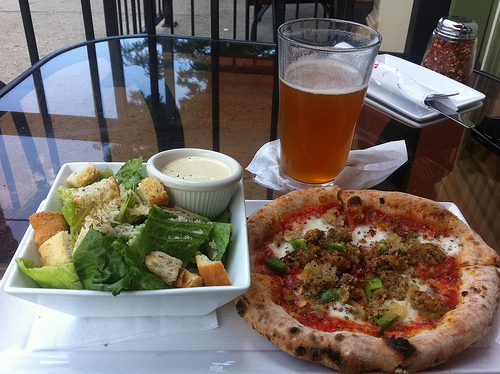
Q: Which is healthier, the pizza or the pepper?
A: The pepper is healthier than the pizza.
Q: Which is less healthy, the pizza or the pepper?
A: The pizza is less healthy than the pepper.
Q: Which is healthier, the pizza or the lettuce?
A: The lettuce is healthier than the pizza.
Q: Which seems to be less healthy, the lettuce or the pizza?
A: The pizza is less healthy than the lettuce.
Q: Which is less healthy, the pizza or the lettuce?
A: The pizza is less healthy than the lettuce.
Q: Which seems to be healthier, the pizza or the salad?
A: The salad is healthier than the pizza.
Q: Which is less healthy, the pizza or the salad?
A: The pizza is less healthy than the salad.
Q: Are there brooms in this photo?
A: No, there are no brooms.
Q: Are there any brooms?
A: No, there are no brooms.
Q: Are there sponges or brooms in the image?
A: No, there are no brooms or sponges.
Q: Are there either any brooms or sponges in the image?
A: No, there are no brooms or sponges.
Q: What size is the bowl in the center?
A: The bowl is small.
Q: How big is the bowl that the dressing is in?
A: The bowl is small.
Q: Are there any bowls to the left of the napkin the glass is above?
A: Yes, there is a bowl to the left of the napkin.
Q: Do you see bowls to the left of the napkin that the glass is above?
A: Yes, there is a bowl to the left of the napkin.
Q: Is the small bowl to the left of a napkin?
A: Yes, the bowl is to the left of a napkin.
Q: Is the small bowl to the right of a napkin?
A: No, the bowl is to the left of a napkin.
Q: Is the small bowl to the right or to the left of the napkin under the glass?
A: The bowl is to the left of the napkin.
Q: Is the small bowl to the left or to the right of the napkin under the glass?
A: The bowl is to the left of the napkin.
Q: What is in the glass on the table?
A: The beverage is in the glass.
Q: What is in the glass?
A: The beverage is in the glass.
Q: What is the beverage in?
A: The beverage is in the glass.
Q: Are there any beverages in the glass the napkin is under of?
A: Yes, there is a beverage in the glass.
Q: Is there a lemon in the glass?
A: No, there is a beverage in the glass.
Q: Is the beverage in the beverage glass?
A: Yes, the beverage is in the glass.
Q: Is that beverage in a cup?
A: No, the beverage is in the glass.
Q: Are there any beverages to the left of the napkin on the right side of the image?
A: Yes, there is a beverage to the left of the napkin.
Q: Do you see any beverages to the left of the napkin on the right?
A: Yes, there is a beverage to the left of the napkin.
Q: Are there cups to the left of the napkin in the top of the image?
A: No, there is a beverage to the left of the napkin.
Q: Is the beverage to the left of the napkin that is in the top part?
A: Yes, the beverage is to the left of the napkin.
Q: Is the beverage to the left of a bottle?
A: No, the beverage is to the left of the napkin.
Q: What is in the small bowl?
A: The dressing is in the bowl.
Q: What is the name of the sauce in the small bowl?
A: The sauce is a dressing.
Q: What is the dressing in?
A: The dressing is in the bowl.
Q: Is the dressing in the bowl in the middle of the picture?
A: Yes, the dressing is in the bowl.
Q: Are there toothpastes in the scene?
A: No, there are no toothpastes.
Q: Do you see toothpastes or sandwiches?
A: No, there are no toothpastes or sandwiches.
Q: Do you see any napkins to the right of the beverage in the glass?
A: Yes, there is a napkin to the right of the beverage.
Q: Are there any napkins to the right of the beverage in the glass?
A: Yes, there is a napkin to the right of the beverage.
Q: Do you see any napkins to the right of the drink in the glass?
A: Yes, there is a napkin to the right of the beverage.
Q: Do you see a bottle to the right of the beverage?
A: No, there is a napkin to the right of the beverage.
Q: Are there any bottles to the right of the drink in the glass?
A: No, there is a napkin to the right of the beverage.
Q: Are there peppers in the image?
A: Yes, there is a pepper.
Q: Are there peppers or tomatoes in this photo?
A: Yes, there is a pepper.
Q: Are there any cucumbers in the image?
A: No, there are no cucumbers.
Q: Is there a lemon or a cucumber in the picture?
A: No, there are no cucumbers or lemons.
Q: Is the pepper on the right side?
A: Yes, the pepper is on the right of the image.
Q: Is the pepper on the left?
A: No, the pepper is on the right of the image.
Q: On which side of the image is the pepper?
A: The pepper is on the right of the image.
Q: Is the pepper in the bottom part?
A: Yes, the pepper is in the bottom of the image.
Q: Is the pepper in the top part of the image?
A: No, the pepper is in the bottom of the image.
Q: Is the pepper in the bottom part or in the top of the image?
A: The pepper is in the bottom of the image.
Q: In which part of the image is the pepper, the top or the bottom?
A: The pepper is in the bottom of the image.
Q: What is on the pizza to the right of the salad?
A: The pepper is on the pizza.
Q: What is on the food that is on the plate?
A: The pepper is on the pizza.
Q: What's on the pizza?
A: The pepper is on the pizza.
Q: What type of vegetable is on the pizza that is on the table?
A: The vegetable is a pepper.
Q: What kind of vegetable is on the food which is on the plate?
A: The vegetable is a pepper.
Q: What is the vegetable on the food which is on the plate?
A: The vegetable is a pepper.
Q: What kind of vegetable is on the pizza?
A: The vegetable is a pepper.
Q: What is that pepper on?
A: The pepper is on the pizza.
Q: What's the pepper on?
A: The pepper is on the pizza.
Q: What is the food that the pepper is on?
A: The food is a pizza.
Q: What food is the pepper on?
A: The pepper is on the pizza.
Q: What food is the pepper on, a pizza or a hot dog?
A: The pepper is on a pizza.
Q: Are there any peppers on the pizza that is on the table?
A: Yes, there is a pepper on the pizza.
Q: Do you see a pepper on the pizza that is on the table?
A: Yes, there is a pepper on the pizza.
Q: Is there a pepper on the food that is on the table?
A: Yes, there is a pepper on the pizza.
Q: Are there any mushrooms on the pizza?
A: No, there is a pepper on the pizza.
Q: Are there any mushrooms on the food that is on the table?
A: No, there is a pepper on the pizza.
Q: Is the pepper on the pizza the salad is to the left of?
A: Yes, the pepper is on the pizza.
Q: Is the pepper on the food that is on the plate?
A: Yes, the pepper is on the pizza.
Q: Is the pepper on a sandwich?
A: No, the pepper is on the pizza.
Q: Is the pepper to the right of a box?
A: No, the pepper is to the right of a bowl.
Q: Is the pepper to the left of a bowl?
A: No, the pepper is to the right of a bowl.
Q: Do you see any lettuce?
A: Yes, there is lettuce.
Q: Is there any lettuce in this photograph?
A: Yes, there is lettuce.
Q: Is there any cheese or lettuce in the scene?
A: Yes, there is lettuce.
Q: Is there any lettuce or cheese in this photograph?
A: Yes, there is lettuce.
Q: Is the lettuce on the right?
A: No, the lettuce is on the left of the image.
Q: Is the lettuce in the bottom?
A: Yes, the lettuce is in the bottom of the image.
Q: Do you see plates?
A: Yes, there is a plate.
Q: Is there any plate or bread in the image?
A: Yes, there is a plate.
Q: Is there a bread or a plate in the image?
A: Yes, there is a plate.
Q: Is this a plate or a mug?
A: This is a plate.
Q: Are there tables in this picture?
A: Yes, there is a table.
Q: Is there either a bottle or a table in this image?
A: Yes, there is a table.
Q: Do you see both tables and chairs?
A: No, there is a table but no chairs.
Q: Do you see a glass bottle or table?
A: Yes, there is a glass table.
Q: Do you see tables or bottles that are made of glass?
A: Yes, the table is made of glass.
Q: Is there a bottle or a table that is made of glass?
A: Yes, the table is made of glass.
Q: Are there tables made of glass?
A: Yes, there is a table that is made of glass.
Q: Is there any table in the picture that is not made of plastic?
A: Yes, there is a table that is made of glass.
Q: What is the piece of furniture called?
A: The piece of furniture is a table.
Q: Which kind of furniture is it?
A: The piece of furniture is a table.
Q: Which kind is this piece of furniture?
A: This is a table.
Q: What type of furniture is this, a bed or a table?
A: This is a table.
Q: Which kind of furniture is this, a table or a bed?
A: This is a table.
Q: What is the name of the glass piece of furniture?
A: The piece of furniture is a table.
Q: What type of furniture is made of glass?
A: The furniture is a table.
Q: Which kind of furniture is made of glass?
A: The furniture is a table.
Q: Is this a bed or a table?
A: This is a table.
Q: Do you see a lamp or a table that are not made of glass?
A: No, there is a table but it is made of glass.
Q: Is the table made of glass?
A: Yes, the table is made of glass.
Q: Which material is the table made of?
A: The table is made of glass.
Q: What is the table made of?
A: The table is made of glass.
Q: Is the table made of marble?
A: No, the table is made of glass.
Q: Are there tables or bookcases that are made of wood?
A: No, there is a table but it is made of glass.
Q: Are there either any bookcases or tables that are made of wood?
A: No, there is a table but it is made of glass.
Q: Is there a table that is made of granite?
A: No, there is a table but it is made of glass.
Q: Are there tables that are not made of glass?
A: No, there is a table but it is made of glass.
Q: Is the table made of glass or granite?
A: The table is made of glass.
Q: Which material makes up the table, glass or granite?
A: The table is made of glass.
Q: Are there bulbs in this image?
A: No, there are no bulbs.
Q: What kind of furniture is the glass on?
A: The glass is on the table.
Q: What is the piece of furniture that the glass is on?
A: The piece of furniture is a table.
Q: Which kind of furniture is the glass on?
A: The glass is on the table.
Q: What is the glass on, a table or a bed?
A: The glass is on a table.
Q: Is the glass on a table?
A: Yes, the glass is on a table.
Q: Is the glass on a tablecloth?
A: No, the glass is on a table.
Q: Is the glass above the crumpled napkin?
A: Yes, the glass is above the napkin.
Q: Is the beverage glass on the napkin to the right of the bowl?
A: Yes, the glass is on the napkin.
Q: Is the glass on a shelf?
A: No, the glass is on the napkin.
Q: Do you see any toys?
A: No, there are no toys.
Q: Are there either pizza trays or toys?
A: No, there are no toys or pizza trays.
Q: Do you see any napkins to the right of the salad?
A: Yes, there is a napkin to the right of the salad.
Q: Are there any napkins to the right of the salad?
A: Yes, there is a napkin to the right of the salad.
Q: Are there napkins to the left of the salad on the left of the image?
A: No, the napkin is to the right of the salad.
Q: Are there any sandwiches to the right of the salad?
A: No, there is a napkin to the right of the salad.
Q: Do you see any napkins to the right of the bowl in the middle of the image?
A: Yes, there is a napkin to the right of the bowl.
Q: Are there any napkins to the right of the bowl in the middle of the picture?
A: Yes, there is a napkin to the right of the bowl.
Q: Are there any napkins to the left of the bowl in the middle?
A: No, the napkin is to the right of the bowl.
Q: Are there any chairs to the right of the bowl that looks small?
A: No, there is a napkin to the right of the bowl.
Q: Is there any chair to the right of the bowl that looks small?
A: No, there is a napkin to the right of the bowl.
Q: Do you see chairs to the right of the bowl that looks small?
A: No, there is a napkin to the right of the bowl.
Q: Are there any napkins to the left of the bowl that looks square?
A: No, the napkin is to the right of the bowl.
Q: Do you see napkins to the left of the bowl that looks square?
A: No, the napkin is to the right of the bowl.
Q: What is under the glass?
A: The napkin is under the glass.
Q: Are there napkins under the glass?
A: Yes, there is a napkin under the glass.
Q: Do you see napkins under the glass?
A: Yes, there is a napkin under the glass.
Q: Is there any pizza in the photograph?
A: Yes, there is a pizza.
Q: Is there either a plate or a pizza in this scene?
A: Yes, there is a pizza.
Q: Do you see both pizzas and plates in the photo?
A: Yes, there are both a pizza and a plate.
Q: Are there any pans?
A: No, there are no pans.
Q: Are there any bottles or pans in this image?
A: No, there are no pans or bottles.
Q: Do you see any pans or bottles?
A: No, there are no pans or bottles.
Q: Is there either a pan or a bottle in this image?
A: No, there are no pans or bottles.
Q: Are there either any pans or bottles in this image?
A: No, there are no pans or bottles.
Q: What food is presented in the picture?
A: The food is a pizza.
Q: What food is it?
A: The food is a pizza.